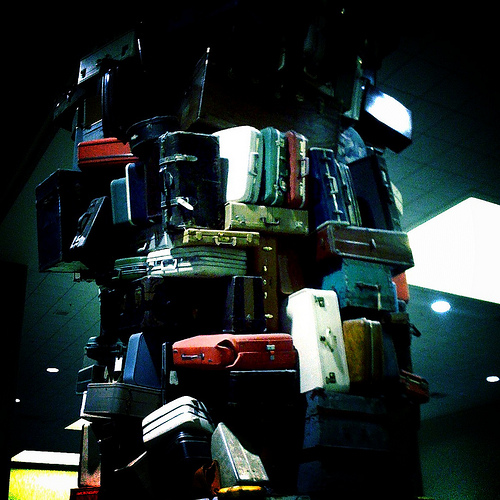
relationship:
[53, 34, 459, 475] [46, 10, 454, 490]
suitcase in stack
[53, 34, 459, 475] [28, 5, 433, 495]
suitcase in stack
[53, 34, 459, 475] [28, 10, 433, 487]
suitcase in pile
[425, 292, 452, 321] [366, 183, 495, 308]
light in ceiling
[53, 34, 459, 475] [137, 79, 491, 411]
suitcase in stack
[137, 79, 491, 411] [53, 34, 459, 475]
stack of suitcase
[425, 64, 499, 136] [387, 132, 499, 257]
tile on ceiling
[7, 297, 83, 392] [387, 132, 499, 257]
vents on ceiling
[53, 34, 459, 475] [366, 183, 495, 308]
suitcase has light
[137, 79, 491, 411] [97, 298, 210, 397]
pile of luggage